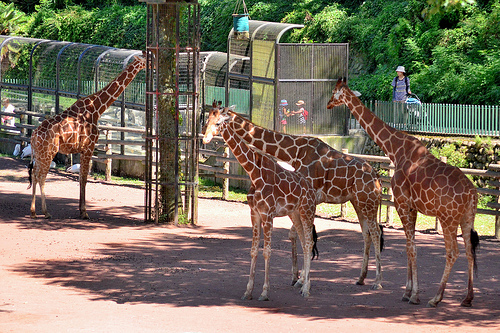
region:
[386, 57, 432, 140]
Woman with Child in Stroller wearing a hat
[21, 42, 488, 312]
four Giraffes in a zoo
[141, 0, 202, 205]
Tree surrounded by a cage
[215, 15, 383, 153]
Perimeter fence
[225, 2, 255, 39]
Pale hanging from tree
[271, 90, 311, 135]
Children sharing treats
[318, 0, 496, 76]
Large bushes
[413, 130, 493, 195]
Perimeter Rock Wall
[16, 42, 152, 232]
Giraffe watching children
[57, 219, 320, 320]
shadow from tree on ground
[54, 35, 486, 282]
four giraffes in a zoo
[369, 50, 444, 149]
a person with a stroller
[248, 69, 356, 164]
two children wearing hats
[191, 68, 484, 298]
three giraffes on one side of the pen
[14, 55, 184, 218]
one giraffe by himself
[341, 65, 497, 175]
a green fence between the giraffes and people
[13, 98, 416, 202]
a wooden fence between the green fence and giraffes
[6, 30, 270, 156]
a tall metal fence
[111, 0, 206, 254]
a tall tree for giraffes to eat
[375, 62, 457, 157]
a person with a purple shirt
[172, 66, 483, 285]
Giraffes at the zoo.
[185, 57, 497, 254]
Three giraffes together.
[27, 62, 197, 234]
One giraffe standing alone.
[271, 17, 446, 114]
Trees behind the enclosure.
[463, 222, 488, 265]
Black tail on the giraffe.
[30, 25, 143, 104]
Metal fence behind the giraffe.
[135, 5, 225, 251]
Pole covering the tree.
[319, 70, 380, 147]
Head of a giraffe.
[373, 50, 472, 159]
People looking at the giraffe.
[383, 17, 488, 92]
Green leaves on the tree.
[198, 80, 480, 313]
Three giraffes standing together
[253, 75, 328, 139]
Two kids playing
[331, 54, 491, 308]
Person watching the giraffes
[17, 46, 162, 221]
A giraffe standing alone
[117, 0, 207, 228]
A tree inside a cage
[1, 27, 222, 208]
The giraffe is fenced in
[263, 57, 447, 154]
people at the zoo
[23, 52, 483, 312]
Four giraffes in the pen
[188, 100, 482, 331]
Giraffes standing in the shade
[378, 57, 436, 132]
A baby carriage at the zoo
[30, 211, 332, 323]
tree's shadow on the ground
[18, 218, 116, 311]
pink ground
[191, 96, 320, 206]
sunlight on giraffe's face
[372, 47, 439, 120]
woman standing with baby carraige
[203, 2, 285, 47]
light green object on a pole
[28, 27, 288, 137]
large clear mesh enclosure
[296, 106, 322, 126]
pink back pack on person's back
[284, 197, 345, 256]
large tail on giraffe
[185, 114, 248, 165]
brown face on giraffe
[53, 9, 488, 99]
large green cluster of trees